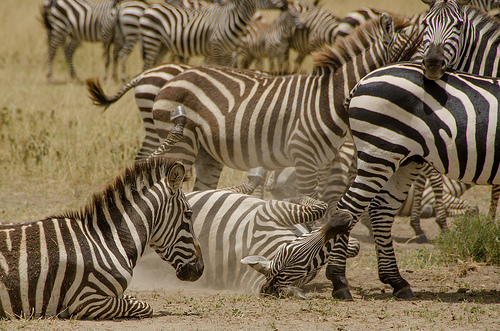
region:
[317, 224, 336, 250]
edge of a leg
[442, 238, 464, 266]
part of a grass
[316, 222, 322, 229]
part of a zebra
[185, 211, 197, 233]
part of an eye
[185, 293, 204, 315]
part of the surface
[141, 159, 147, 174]
part of a hair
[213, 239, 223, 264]
back of a zebra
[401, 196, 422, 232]
edge of a leg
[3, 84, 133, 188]
tall dried golden grass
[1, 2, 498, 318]
herd of zebra facing right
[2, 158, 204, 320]
front side of reclined zebra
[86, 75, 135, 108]
moving tail of zebra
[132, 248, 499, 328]
kicked up dust from ground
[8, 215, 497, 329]
dirt on surface of ground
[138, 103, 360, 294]
zebra laying on back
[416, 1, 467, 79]
zebra head facing camera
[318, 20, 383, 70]
mane on zebra neck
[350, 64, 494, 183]
stripes on hind quarter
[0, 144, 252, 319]
this is a zebra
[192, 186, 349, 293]
this is a zebra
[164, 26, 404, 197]
this is a zebra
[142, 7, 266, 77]
this is a zebra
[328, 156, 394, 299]
this is aleg of a zebra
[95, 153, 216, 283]
this is a head of a zebra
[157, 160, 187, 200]
this is an ear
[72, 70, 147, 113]
this is a tail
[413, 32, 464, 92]
this is a mouth of a zebra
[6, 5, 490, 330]
this isa grazing land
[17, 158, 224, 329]
the zebra is sitting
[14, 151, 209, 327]
the zebra is sitting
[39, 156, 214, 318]
the zebra is sitting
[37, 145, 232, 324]
the zebra is sitting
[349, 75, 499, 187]
black and white stripes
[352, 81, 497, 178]
black and white stripes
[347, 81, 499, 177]
black and white stripes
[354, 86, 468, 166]
black and white stripes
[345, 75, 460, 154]
black and white stripes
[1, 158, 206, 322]
A zebra on the ground.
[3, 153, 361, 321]
Two zebras in the dirt.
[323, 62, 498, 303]
Part of a zebra.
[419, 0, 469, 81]
A zebras head and face.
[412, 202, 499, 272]
A green bush on the ground.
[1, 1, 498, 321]
A bunch of zebras.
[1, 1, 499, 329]
Zebras in a field.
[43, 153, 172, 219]
A zebras hairy mane.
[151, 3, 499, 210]
Two zebras in a field.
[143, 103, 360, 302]
A zebra on its back.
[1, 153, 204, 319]
zebra next to zebra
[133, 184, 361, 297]
zebra next to zebra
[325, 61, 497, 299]
zebra next to zebra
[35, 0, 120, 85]
zebra next to zebra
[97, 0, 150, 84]
zebra next to zebra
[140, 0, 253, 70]
zebra next to zebra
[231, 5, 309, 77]
zebra next to zebra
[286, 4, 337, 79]
zebra next to zebra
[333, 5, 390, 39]
zebra next to zebra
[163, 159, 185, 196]
Ear of a zebra